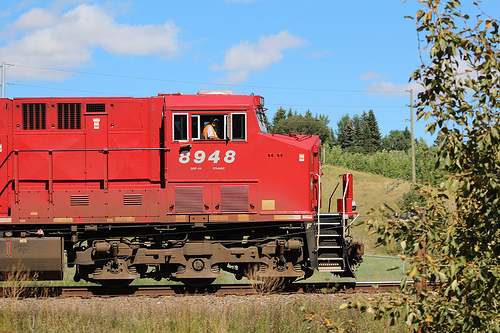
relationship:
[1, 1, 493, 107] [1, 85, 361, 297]
sky above train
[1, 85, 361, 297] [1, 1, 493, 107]
train below sky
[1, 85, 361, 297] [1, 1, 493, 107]
train under sky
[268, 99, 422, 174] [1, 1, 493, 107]
trees under sky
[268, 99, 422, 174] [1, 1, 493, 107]
trees below sky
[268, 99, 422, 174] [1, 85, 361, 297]
trees beside train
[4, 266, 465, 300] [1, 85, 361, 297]
tracks under train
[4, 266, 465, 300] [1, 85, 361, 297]
tracks below train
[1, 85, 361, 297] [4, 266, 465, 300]
train on tracks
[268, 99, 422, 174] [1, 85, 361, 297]
trees next to train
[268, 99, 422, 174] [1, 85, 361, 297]
trees close to train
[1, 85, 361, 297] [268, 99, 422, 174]
train near trees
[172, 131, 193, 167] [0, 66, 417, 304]
number on train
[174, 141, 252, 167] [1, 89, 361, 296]
number on train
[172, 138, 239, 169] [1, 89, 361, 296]
number on train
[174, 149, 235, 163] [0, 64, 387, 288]
number on train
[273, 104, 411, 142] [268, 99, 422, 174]
leaves are on trees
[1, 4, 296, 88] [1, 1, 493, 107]
clouds are in sky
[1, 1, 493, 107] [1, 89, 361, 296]
sky in train